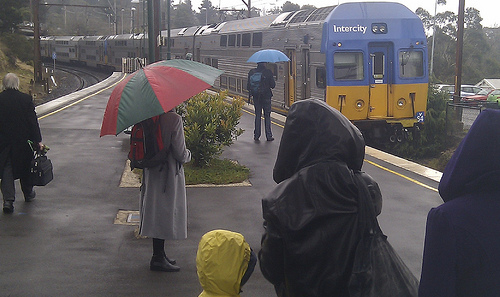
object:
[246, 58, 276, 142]
man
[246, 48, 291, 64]
umbrella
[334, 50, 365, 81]
window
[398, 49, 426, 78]
window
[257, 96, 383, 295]
raincoat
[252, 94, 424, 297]
person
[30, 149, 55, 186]
briefcase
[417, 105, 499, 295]
cloak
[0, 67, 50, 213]
man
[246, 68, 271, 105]
backpack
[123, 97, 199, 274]
woman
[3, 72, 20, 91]
hair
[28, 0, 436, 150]
train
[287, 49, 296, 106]
door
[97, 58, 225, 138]
umbrella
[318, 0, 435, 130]
front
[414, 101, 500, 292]
person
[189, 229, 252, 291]
hood